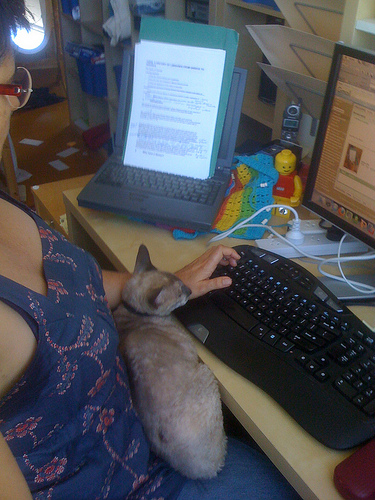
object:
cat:
[112, 241, 230, 480]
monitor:
[298, 41, 374, 250]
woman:
[0, 0, 303, 500]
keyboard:
[173, 244, 374, 451]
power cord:
[206, 203, 374, 295]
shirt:
[0, 190, 169, 500]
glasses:
[0, 64, 34, 110]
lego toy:
[266, 148, 303, 219]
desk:
[62, 155, 375, 500]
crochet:
[171, 149, 279, 242]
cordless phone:
[281, 96, 304, 139]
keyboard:
[94, 161, 221, 209]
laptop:
[77, 45, 249, 234]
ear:
[133, 244, 154, 275]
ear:
[153, 284, 170, 308]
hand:
[172, 243, 242, 299]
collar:
[118, 298, 149, 319]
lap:
[148, 420, 287, 499]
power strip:
[253, 233, 369, 258]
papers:
[122, 37, 227, 180]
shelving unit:
[120, 14, 241, 178]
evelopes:
[18, 135, 45, 148]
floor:
[7, 82, 109, 211]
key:
[263, 329, 279, 346]